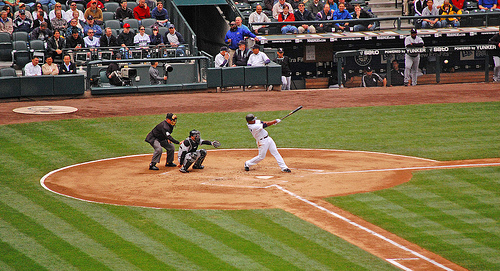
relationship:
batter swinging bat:
[244, 114, 291, 173] [275, 97, 310, 126]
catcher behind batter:
[175, 128, 220, 171] [241, 111, 291, 172]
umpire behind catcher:
[145, 113, 184, 171] [172, 126, 220, 173]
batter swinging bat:
[243, 114, 295, 175] [275, 103, 305, 122]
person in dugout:
[401, 28, 426, 86] [259, 25, 499, 88]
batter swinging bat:
[244, 114, 291, 173] [277, 102, 302, 122]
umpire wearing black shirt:
[145, 113, 184, 171] [145, 120, 180, 144]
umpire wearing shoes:
[145, 113, 184, 171] [146, 157, 175, 173]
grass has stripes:
[1, 100, 499, 270] [4, 106, 498, 268]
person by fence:
[401, 32, 426, 86] [332, 40, 499, 89]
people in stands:
[0, 0, 498, 96] [0, 1, 498, 88]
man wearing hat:
[116, 20, 135, 46] [121, 20, 131, 32]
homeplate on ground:
[253, 171, 276, 185] [2, 84, 497, 269]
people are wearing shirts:
[224, 13, 258, 49] [235, 123, 285, 153]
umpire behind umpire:
[143, 110, 180, 175] [145, 113, 184, 171]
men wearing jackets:
[223, 15, 263, 52] [144, 111, 176, 148]